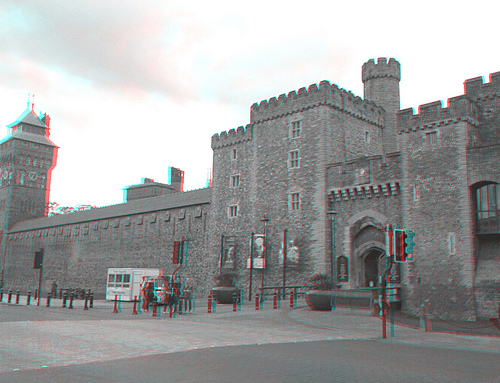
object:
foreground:
[0, 314, 500, 383]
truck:
[104, 267, 161, 301]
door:
[347, 215, 393, 313]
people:
[161, 279, 174, 314]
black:
[145, 287, 155, 309]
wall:
[0, 186, 211, 301]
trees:
[44, 200, 97, 218]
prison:
[208, 45, 410, 304]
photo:
[0, 0, 500, 383]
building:
[208, 45, 475, 320]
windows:
[287, 191, 301, 210]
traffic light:
[392, 223, 408, 263]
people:
[140, 276, 153, 314]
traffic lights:
[173, 240, 181, 264]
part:
[264, 329, 304, 352]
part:
[393, 251, 402, 261]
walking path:
[0, 298, 360, 373]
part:
[184, 329, 209, 350]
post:
[380, 223, 392, 337]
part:
[379, 287, 386, 297]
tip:
[357, 57, 402, 71]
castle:
[209, 57, 500, 319]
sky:
[0, 0, 500, 217]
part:
[72, 140, 97, 165]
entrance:
[359, 242, 386, 296]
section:
[372, 254, 384, 270]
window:
[287, 149, 301, 169]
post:
[33, 246, 44, 307]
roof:
[6, 104, 51, 128]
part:
[30, 116, 40, 126]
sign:
[247, 233, 264, 268]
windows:
[226, 203, 239, 219]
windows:
[228, 173, 241, 189]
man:
[369, 280, 384, 316]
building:
[0, 57, 500, 323]